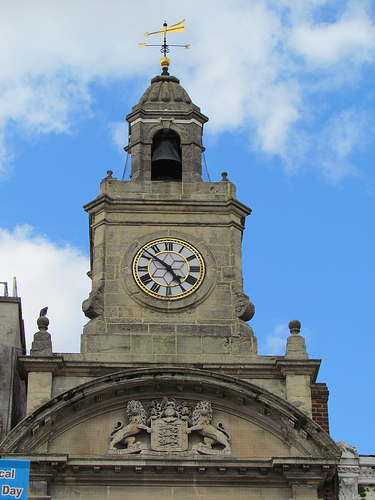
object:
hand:
[166, 265, 181, 284]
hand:
[142, 248, 172, 271]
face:
[200, 403, 208, 416]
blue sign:
[0, 458, 32, 499]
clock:
[121, 230, 217, 313]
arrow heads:
[144, 31, 149, 38]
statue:
[148, 396, 192, 452]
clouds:
[0, 0, 375, 353]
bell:
[151, 141, 181, 163]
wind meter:
[138, 19, 191, 70]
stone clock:
[80, 18, 259, 354]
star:
[152, 253, 186, 285]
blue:
[255, 188, 375, 314]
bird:
[39, 306, 48, 317]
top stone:
[37, 316, 50, 326]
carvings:
[108, 400, 155, 455]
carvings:
[183, 400, 232, 457]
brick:
[311, 382, 330, 437]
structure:
[6, 363, 338, 453]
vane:
[144, 19, 186, 38]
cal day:
[0, 466, 24, 498]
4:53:
[133, 237, 207, 301]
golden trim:
[131, 235, 207, 301]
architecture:
[0, 19, 375, 500]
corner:
[1, 458, 36, 499]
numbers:
[165, 286, 172, 296]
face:
[132, 238, 206, 301]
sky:
[3, 0, 375, 456]